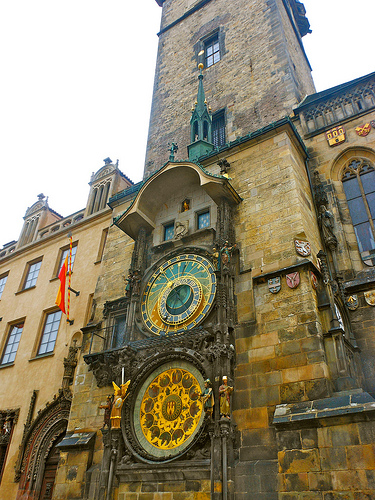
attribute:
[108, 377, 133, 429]
angle statue —  gold,  of angel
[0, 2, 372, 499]
building — with Roman letter clock, big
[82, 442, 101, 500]
door —  heavy ,  wood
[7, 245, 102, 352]
windows — glass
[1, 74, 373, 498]
wall —  old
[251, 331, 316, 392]
wall —  rusty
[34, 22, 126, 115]
sky —   white 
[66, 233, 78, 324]
pole — metal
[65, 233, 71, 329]
pole — orange, yellow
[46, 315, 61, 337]
window —  closed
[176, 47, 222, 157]
steeple —  dark green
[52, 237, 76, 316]
flag — orange, yellow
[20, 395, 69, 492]
arhway —  large,  decorative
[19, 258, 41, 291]
window — closed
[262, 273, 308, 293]
shields — in row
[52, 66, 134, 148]
clouds — white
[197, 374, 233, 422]
small statues —  small ,  a pair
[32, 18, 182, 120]
sky — bright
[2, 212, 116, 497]
wall — brown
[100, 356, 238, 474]
decor — gold